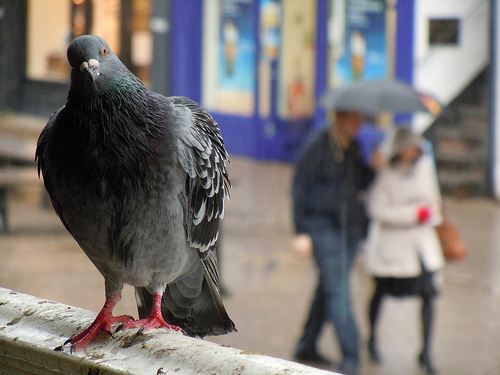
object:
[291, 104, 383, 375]
man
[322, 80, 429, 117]
umbrella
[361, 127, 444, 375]
woman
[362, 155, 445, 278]
coat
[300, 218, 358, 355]
jeans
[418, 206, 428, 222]
glove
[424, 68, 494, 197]
steps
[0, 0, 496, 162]
store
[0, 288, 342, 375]
railing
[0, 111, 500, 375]
street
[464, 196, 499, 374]
rightward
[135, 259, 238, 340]
tail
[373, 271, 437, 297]
skirt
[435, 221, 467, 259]
bag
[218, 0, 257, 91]
sign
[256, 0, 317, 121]
window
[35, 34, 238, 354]
foreground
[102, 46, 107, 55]
eye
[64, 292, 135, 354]
claws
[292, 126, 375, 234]
jacket